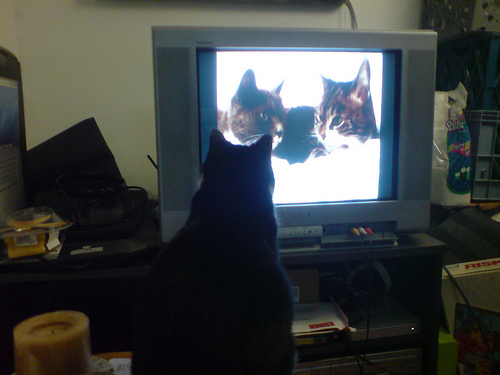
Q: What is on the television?
A: Cats.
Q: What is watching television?
A: A cat.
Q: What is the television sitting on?
A: A stand.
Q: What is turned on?
A: The television.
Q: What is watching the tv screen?
A: A cat.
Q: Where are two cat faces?
A: On a tv screen.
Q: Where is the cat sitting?
A: On the table.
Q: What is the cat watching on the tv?
A: Cats.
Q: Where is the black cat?
A: Sitting on the table.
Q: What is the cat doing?
A: Watching television.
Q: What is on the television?
A: Two cats.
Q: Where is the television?
A: On a table.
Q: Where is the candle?
A: Front left of the photo.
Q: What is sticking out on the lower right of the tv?
A: Cords.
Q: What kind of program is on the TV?
A: Cat program.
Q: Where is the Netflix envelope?
A: On the shelf under the television.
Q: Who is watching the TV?
A: A cat.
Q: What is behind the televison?
A: The wall.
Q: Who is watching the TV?
A: The cat.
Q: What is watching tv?
A: Cat.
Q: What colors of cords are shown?
A: Red, white, yellow.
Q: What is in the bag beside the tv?
A: Toilet paper.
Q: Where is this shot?
A: Living room.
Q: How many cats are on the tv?
A: 3.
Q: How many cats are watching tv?
A: 1.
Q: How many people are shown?
A: 0.